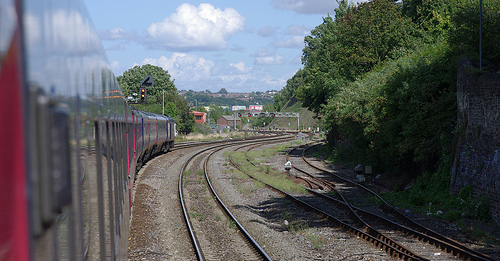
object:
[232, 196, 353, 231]
shade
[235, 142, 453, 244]
shadow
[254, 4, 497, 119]
trees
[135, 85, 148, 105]
lights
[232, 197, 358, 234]
shadow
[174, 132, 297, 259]
track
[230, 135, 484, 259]
track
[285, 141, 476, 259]
track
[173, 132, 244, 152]
track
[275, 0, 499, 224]
shrubs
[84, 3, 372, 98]
clouds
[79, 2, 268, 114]
sky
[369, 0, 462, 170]
tree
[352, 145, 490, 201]
embankment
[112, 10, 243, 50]
clouds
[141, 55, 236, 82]
clouds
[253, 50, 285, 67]
clouds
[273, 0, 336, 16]
clouds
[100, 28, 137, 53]
clouds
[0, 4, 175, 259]
train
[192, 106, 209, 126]
building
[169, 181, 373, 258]
tracks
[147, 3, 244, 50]
cloud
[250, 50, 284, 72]
cloud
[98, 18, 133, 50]
cloud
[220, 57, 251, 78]
cloud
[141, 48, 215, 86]
cloud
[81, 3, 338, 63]
sky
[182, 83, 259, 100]
big mountain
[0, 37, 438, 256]
train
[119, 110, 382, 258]
track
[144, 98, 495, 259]
tracks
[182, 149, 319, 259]
rails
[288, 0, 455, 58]
trees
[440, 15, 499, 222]
wall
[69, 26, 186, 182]
train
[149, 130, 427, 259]
rail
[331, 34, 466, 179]
shrubbery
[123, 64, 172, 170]
traffic light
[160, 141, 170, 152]
wheel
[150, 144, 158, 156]
wheel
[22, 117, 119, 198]
train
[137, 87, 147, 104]
light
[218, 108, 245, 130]
building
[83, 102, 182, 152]
train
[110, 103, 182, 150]
train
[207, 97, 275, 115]
billboards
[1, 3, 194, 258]
train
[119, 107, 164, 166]
doorways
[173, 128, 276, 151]
tracks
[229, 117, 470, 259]
tracks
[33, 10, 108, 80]
cloud reflection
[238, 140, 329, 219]
grass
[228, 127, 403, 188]
tracks